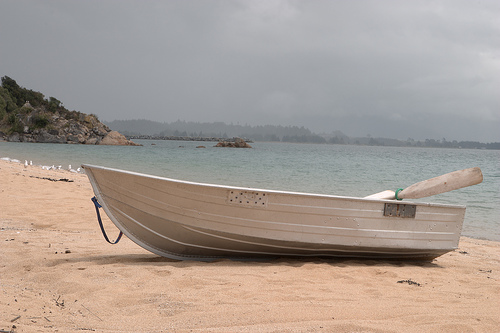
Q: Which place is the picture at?
A: It is at the beach.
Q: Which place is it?
A: It is a beach.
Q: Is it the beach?
A: Yes, it is the beach.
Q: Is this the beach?
A: Yes, it is the beach.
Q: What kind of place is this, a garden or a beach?
A: It is a beach.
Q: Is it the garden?
A: No, it is the beach.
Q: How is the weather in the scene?
A: It is cloudy.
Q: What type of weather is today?
A: It is cloudy.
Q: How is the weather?
A: It is cloudy.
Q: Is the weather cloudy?
A: Yes, it is cloudy.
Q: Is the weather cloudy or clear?
A: It is cloudy.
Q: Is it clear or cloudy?
A: It is cloudy.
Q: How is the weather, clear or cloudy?
A: It is cloudy.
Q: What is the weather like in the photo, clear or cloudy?
A: It is cloudy.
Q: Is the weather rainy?
A: No, it is cloudy.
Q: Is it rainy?
A: No, it is cloudy.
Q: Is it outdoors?
A: Yes, it is outdoors.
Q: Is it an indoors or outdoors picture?
A: It is outdoors.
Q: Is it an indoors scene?
A: No, it is outdoors.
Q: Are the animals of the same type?
A: Yes, all the animals are seagulls.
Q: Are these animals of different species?
A: No, all the animals are seagulls.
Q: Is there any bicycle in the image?
A: No, there are no bicycles.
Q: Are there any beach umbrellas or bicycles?
A: No, there are no bicycles or beach umbrellas.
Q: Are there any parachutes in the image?
A: No, there are no parachutes.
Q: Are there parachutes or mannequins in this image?
A: No, there are no parachutes or mannequins.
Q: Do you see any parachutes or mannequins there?
A: No, there are no parachutes or mannequins.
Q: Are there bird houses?
A: No, there are no bird houses.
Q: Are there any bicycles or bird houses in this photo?
A: No, there are no bird houses or bicycles.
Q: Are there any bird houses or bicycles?
A: No, there are no bird houses or bicycles.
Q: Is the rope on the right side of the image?
A: No, the rope is on the left of the image.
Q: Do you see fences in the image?
A: No, there are no fences.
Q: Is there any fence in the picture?
A: No, there are no fences.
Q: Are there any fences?
A: No, there are no fences.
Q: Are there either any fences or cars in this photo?
A: No, there are no fences or cars.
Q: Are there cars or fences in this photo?
A: No, there are no fences or cars.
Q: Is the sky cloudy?
A: Yes, the sky is cloudy.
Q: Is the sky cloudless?
A: No, the sky is cloudy.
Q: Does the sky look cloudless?
A: No, the sky is cloudy.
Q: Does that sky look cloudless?
A: No, the sky is cloudy.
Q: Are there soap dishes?
A: No, there are no soap dishes.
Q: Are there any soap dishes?
A: No, there are no soap dishes.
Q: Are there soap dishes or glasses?
A: No, there are no soap dishes or glasses.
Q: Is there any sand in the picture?
A: Yes, there is sand.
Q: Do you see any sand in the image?
A: Yes, there is sand.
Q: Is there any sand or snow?
A: Yes, there is sand.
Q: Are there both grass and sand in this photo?
A: No, there is sand but no grass.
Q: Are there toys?
A: No, there are no toys.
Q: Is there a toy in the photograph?
A: No, there are no toys.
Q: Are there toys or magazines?
A: No, there are no toys or magazines.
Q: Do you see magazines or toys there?
A: No, there are no toys or magazines.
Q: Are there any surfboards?
A: No, there are no surfboards.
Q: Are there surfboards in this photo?
A: No, there are no surfboards.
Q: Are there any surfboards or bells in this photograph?
A: No, there are no surfboards or bells.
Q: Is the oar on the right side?
A: Yes, the oar is on the right of the image.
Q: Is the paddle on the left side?
A: No, the paddle is on the right of the image.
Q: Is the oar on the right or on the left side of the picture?
A: The oar is on the right of the image.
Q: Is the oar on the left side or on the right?
A: The oar is on the right of the image.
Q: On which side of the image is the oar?
A: The oar is on the right of the image.